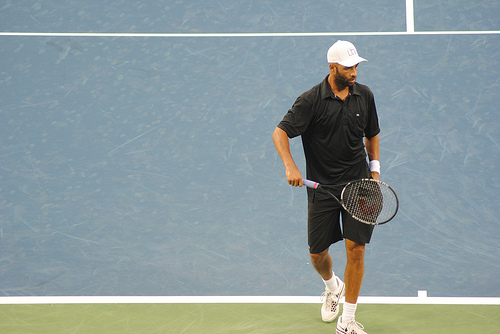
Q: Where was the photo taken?
A: It was taken at the field.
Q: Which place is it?
A: It is a field.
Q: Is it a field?
A: Yes, it is a field.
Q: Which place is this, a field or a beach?
A: It is a field.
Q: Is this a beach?
A: No, it is a field.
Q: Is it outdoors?
A: Yes, it is outdoors.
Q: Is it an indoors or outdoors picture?
A: It is outdoors.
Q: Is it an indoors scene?
A: No, it is outdoors.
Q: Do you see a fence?
A: No, there are no fences.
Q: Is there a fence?
A: No, there are no fences.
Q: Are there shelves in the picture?
A: No, there are no shelves.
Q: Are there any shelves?
A: No, there are no shelves.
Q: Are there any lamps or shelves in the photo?
A: No, there are no shelves or lamps.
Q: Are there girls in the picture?
A: No, there are no girls.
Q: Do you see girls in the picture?
A: No, there are no girls.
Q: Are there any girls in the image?
A: No, there are no girls.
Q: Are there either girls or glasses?
A: No, there are no girls or glasses.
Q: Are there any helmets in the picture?
A: No, there are no helmets.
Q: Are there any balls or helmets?
A: No, there are no helmets or balls.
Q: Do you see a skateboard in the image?
A: No, there are no skateboards.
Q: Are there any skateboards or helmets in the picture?
A: No, there are no skateboards or helmets.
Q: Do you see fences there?
A: No, there are no fences.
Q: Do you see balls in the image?
A: No, there are no balls.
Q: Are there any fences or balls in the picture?
A: No, there are no balls or fences.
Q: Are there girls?
A: No, there are no girls.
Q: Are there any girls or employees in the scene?
A: No, there are no girls or employees.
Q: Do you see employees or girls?
A: No, there are no girls or employees.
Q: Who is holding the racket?
A: The man is holding the racket.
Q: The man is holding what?
A: The man is holding the racket.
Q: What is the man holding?
A: The man is holding the racket.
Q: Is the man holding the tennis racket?
A: Yes, the man is holding the tennis racket.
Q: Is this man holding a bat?
A: No, the man is holding the tennis racket.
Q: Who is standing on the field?
A: The man is standing on the field.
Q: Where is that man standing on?
A: The man is standing on the field.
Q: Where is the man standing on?
A: The man is standing on the field.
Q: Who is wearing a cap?
A: The man is wearing a cap.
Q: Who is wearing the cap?
A: The man is wearing a cap.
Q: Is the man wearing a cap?
A: Yes, the man is wearing a cap.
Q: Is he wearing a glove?
A: No, the man is wearing a cap.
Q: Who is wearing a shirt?
A: The man is wearing a shirt.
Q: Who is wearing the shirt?
A: The man is wearing a shirt.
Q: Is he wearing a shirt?
A: Yes, the man is wearing a shirt.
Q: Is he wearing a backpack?
A: No, the man is wearing a shirt.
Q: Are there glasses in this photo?
A: No, there are no glasses.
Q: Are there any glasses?
A: No, there are no glasses.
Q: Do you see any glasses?
A: No, there are no glasses.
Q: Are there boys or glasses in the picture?
A: No, there are no glasses or boys.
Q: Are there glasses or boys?
A: No, there are no glasses or boys.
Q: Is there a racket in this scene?
A: Yes, there is a racket.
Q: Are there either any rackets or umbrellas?
A: Yes, there is a racket.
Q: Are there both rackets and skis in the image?
A: No, there is a racket but no skis.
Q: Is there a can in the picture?
A: No, there are no cans.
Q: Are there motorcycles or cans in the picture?
A: No, there are no cans or motorcycles.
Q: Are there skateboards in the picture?
A: No, there are no skateboards.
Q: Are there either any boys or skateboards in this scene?
A: No, there are no skateboards or boys.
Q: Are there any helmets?
A: No, there are no helmets.